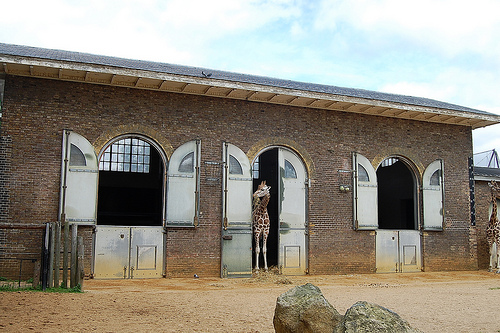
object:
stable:
[58, 127, 200, 280]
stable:
[218, 137, 315, 276]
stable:
[352, 150, 443, 272]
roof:
[0, 43, 500, 129]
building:
[0, 42, 500, 281]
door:
[222, 141, 254, 280]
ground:
[359, 173, 369, 195]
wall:
[10, 113, 52, 188]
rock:
[273, 283, 345, 332]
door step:
[83, 271, 499, 292]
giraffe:
[252, 180, 270, 274]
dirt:
[390, 287, 469, 332]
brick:
[0, 74, 471, 270]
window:
[89, 135, 168, 175]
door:
[350, 152, 379, 232]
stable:
[0, 35, 480, 288]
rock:
[341, 301, 425, 332]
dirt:
[34, 259, 484, 332]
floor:
[117, 277, 492, 284]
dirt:
[253, 266, 291, 285]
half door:
[423, 158, 445, 231]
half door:
[164, 139, 200, 228]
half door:
[57, 129, 99, 226]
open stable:
[353, 129, 437, 276]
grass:
[0, 279, 84, 294]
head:
[253, 180, 272, 197]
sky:
[0, 0, 485, 154]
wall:
[3, 72, 485, 272]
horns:
[261, 181, 264, 185]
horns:
[264, 181, 267, 185]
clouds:
[0, 0, 499, 150]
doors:
[277, 146, 308, 276]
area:
[0, 272, 499, 333]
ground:
[104, 299, 499, 333]